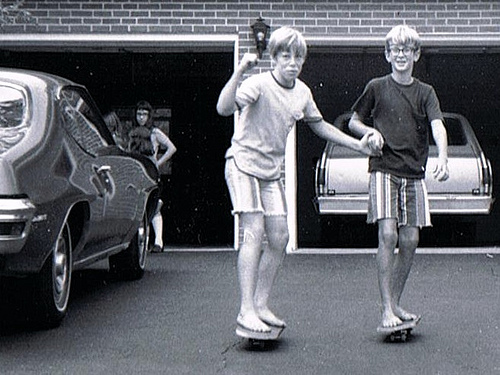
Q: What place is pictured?
A: It is a sidewalk.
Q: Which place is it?
A: It is a sidewalk.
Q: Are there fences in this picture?
A: No, there are no fences.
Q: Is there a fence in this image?
A: No, there are no fences.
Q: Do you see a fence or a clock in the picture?
A: No, there are no fences or clocks.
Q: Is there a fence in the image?
A: No, there are no fences.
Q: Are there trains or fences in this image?
A: No, there are no fences or trains.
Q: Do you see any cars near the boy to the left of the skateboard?
A: Yes, there is a car near the boy.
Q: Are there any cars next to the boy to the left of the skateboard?
A: Yes, there is a car next to the boy.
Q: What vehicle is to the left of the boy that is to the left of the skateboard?
A: The vehicle is a car.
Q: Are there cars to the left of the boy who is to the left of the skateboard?
A: Yes, there is a car to the left of the boy.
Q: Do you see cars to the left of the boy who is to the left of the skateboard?
A: Yes, there is a car to the left of the boy.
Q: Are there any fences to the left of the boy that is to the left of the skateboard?
A: No, there is a car to the left of the boy.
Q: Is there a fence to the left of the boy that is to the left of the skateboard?
A: No, there is a car to the left of the boy.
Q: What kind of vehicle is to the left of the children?
A: The vehicle is a car.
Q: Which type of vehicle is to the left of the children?
A: The vehicle is a car.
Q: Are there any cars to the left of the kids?
A: Yes, there is a car to the left of the kids.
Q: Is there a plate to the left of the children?
A: No, there is a car to the left of the children.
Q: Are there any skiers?
A: No, there are no skiers.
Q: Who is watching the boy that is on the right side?
A: The girl is watching the boy.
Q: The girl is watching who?
A: The girl is watching the boy.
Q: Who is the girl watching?
A: The girl is watching the boy.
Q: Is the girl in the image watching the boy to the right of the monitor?
A: Yes, the girl is watching the boy.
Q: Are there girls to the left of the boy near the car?
A: Yes, there is a girl to the left of the boy.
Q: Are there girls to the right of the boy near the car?
A: No, the girl is to the left of the boy.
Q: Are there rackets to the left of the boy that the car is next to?
A: No, there is a girl to the left of the boy.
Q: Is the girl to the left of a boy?
A: Yes, the girl is to the left of a boy.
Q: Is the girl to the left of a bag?
A: No, the girl is to the left of a boy.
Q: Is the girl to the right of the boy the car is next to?
A: No, the girl is to the left of the boy.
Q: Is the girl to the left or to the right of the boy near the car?
A: The girl is to the left of the boy.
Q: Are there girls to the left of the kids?
A: Yes, there is a girl to the left of the kids.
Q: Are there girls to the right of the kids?
A: No, the girl is to the left of the kids.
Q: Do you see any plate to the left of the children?
A: No, there is a girl to the left of the children.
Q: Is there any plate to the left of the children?
A: No, there is a girl to the left of the children.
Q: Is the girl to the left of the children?
A: Yes, the girl is to the left of the children.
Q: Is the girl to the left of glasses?
A: No, the girl is to the left of the children.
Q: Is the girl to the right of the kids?
A: No, the girl is to the left of the kids.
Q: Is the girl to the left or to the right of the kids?
A: The girl is to the left of the kids.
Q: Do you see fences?
A: No, there are no fences.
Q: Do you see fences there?
A: No, there are no fences.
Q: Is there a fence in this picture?
A: No, there are no fences.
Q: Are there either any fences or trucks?
A: No, there are no fences or trucks.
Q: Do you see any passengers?
A: No, there are no passengers.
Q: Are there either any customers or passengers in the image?
A: No, there are no passengers or customers.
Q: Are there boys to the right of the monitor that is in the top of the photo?
A: Yes, there is a boy to the right of the monitor.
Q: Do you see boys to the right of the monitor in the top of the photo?
A: Yes, there is a boy to the right of the monitor.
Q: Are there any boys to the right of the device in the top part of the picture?
A: Yes, there is a boy to the right of the monitor.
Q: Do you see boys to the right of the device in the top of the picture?
A: Yes, there is a boy to the right of the monitor.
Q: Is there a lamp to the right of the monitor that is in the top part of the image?
A: No, there is a boy to the right of the monitor.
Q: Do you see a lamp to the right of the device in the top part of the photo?
A: No, there is a boy to the right of the monitor.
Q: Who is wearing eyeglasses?
A: The boy is wearing eyeglasses.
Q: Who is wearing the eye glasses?
A: The boy is wearing eyeglasses.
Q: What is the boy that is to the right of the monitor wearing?
A: The boy is wearing eyeglasses.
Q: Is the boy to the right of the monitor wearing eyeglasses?
A: Yes, the boy is wearing eyeglasses.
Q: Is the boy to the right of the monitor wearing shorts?
A: No, the boy is wearing eyeglasses.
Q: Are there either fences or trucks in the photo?
A: No, there are no fences or trucks.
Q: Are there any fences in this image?
A: No, there are no fences.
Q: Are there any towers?
A: No, there are no towers.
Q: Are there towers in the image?
A: No, there are no towers.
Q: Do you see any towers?
A: No, there are no towers.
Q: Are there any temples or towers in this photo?
A: No, there are no towers or temples.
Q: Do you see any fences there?
A: No, there are no fences.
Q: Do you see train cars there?
A: No, there are no train cars.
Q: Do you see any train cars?
A: No, there are no train cars.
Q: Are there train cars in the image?
A: No, there are no train cars.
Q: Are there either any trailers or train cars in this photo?
A: No, there are no train cars or trailers.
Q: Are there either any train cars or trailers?
A: No, there are no train cars or trailers.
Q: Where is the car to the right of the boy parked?
A: The car is parked in the garage.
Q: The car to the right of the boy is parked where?
A: The car is parked in the garage.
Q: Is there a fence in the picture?
A: No, there are no fences.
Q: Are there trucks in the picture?
A: No, there are no trucks.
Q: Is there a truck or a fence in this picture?
A: No, there are no trucks or fences.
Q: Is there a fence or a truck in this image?
A: No, there are no trucks or fences.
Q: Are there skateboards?
A: Yes, there is a skateboard.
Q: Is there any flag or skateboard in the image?
A: Yes, there is a skateboard.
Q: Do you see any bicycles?
A: No, there are no bicycles.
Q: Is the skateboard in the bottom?
A: Yes, the skateboard is in the bottom of the image.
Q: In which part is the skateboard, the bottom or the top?
A: The skateboard is in the bottom of the image.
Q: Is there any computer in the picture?
A: No, there are no computers.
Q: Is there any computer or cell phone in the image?
A: No, there are no computers or cell phones.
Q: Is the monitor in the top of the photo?
A: Yes, the monitor is in the top of the image.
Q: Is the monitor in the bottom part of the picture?
A: No, the monitor is in the top of the image.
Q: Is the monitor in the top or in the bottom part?
A: The monitor is in the top of the image.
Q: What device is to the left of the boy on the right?
A: The device is a monitor.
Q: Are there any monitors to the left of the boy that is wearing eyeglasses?
A: Yes, there is a monitor to the left of the boy.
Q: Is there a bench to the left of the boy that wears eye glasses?
A: No, there is a monitor to the left of the boy.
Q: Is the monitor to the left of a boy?
A: Yes, the monitor is to the left of a boy.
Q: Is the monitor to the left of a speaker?
A: No, the monitor is to the left of a boy.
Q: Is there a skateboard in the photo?
A: Yes, there is a skateboard.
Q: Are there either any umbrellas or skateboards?
A: Yes, there is a skateboard.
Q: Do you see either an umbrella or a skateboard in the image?
A: Yes, there is a skateboard.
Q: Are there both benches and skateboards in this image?
A: No, there is a skateboard but no benches.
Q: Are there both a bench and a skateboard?
A: No, there is a skateboard but no benches.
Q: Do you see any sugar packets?
A: No, there are no sugar packets.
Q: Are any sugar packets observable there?
A: No, there are no sugar packets.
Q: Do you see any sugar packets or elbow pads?
A: No, there are no sugar packets or elbow pads.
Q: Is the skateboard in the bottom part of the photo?
A: Yes, the skateboard is in the bottom of the image.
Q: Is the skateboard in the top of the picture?
A: No, the skateboard is in the bottom of the image.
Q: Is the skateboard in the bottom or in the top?
A: The skateboard is in the bottom of the image.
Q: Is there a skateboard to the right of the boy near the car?
A: Yes, there is a skateboard to the right of the boy.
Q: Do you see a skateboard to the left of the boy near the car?
A: No, the skateboard is to the right of the boy.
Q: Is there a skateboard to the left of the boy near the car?
A: No, the skateboard is to the right of the boy.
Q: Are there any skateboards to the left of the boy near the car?
A: No, the skateboard is to the right of the boy.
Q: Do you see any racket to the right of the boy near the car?
A: No, there is a skateboard to the right of the boy.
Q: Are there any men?
A: No, there are no men.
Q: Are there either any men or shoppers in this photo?
A: No, there are no men or shoppers.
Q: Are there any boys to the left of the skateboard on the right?
A: Yes, there is a boy to the left of the skateboard.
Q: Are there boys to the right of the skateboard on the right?
A: No, the boy is to the left of the skateboard.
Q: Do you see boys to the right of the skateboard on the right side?
A: No, the boy is to the left of the skateboard.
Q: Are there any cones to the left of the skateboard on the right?
A: No, there is a boy to the left of the skateboard.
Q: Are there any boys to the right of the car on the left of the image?
A: Yes, there is a boy to the right of the car.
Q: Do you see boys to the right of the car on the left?
A: Yes, there is a boy to the right of the car.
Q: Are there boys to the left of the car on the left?
A: No, the boy is to the right of the car.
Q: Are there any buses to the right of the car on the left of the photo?
A: No, there is a boy to the right of the car.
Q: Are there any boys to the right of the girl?
A: Yes, there is a boy to the right of the girl.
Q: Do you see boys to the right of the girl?
A: Yes, there is a boy to the right of the girl.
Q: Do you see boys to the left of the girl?
A: No, the boy is to the right of the girl.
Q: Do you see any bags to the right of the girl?
A: No, there is a boy to the right of the girl.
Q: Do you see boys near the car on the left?
A: Yes, there is a boy near the car.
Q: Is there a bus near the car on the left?
A: No, there is a boy near the car.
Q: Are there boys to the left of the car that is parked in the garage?
A: Yes, there is a boy to the left of the car.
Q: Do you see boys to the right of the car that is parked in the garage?
A: No, the boy is to the left of the car.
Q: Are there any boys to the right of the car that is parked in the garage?
A: No, the boy is to the left of the car.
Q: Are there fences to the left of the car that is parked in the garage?
A: No, there is a boy to the left of the car.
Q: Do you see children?
A: Yes, there are children.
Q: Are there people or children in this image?
A: Yes, there are children.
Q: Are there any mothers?
A: No, there are no mothers.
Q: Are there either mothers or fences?
A: No, there are no mothers or fences.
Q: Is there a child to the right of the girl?
A: Yes, there are children to the right of the girl.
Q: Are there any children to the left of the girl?
A: No, the children are to the right of the girl.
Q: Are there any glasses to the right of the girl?
A: No, there are children to the right of the girl.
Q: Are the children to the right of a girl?
A: Yes, the children are to the right of a girl.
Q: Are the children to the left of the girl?
A: No, the children are to the right of the girl.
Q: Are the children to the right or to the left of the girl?
A: The children are to the right of the girl.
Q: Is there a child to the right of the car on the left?
A: Yes, there are children to the right of the car.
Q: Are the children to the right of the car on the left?
A: Yes, the children are to the right of the car.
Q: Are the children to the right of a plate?
A: No, the children are to the right of the car.